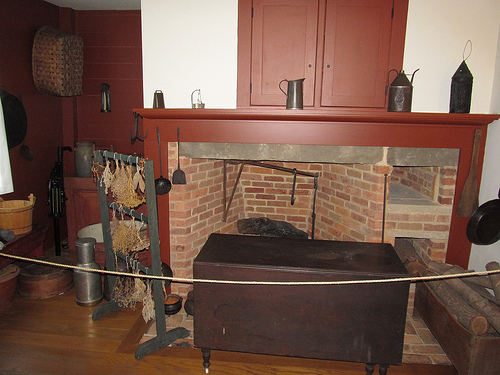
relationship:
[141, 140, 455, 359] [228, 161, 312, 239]
brick in wall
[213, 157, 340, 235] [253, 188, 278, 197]
wall has brick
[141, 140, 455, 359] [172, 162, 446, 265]
brick in wall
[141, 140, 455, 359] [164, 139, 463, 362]
brick on fireplace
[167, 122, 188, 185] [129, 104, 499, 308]
tool hanging from fireplace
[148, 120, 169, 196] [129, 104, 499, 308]
tool hanging from fireplace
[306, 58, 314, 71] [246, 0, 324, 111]
dot on cabinet door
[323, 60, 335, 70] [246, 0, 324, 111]
dot on cabinet door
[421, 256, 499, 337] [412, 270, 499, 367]
firewood in container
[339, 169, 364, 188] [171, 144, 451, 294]
brick in wall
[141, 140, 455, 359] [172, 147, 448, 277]
brick in wall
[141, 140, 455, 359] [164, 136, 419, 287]
brick in wall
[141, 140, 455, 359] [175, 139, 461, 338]
brick in wall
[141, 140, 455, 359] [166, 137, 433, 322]
brick in wall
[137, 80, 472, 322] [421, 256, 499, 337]
fireplace has firewood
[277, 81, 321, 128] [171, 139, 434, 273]
container on fireplace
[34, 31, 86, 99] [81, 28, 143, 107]
basket on wall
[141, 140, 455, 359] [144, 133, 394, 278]
brick on fireplace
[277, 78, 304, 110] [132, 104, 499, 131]
container on mantle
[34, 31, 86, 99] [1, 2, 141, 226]
basket hanging on wall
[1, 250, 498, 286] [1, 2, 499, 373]
rope blocking off exhibit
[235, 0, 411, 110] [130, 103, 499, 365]
cabinets above fireplace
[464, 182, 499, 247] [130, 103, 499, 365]
frying pan hanging next to fireplace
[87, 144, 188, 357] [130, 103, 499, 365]
drying rack next to fireplace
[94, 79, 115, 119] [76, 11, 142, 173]
lantern on wall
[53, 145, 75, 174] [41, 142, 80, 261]
handle on water pump